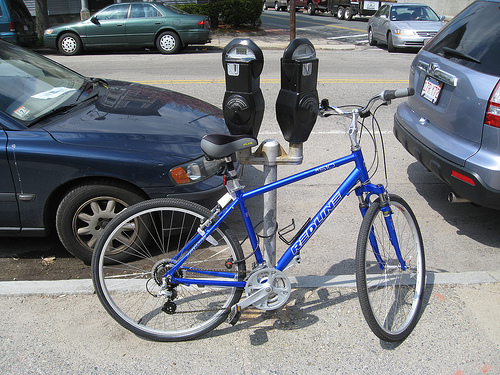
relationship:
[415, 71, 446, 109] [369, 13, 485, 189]
tag on vehicle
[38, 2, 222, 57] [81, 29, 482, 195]
car on street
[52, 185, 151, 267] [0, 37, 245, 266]
tire on car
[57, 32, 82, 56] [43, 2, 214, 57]
tire on car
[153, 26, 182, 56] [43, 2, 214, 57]
tire on car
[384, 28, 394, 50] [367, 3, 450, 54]
tire on car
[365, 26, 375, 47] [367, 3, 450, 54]
tire on car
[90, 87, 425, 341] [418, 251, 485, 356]
bicycle on sidewalk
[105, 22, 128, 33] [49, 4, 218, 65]
handle door on car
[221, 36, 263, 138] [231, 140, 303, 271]
parking meter on a post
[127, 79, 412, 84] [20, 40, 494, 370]
lines on a street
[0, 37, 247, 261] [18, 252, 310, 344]
car next to a curb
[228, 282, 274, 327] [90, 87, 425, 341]
foot peddles on bicycle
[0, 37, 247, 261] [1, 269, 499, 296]
car parked next to curb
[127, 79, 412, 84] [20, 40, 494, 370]
lines painted on street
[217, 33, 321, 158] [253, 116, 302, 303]
meter on pole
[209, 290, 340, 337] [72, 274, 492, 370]
shadow on sidewalk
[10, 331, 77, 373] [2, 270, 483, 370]
gravel on sidewalk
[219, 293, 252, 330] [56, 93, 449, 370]
pedal on bike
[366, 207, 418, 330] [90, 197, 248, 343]
spokes on tire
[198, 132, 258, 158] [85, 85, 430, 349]
seat on bike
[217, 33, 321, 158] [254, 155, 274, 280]
meter on post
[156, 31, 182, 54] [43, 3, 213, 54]
tire on car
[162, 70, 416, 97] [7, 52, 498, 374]
paint on road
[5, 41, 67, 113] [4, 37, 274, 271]
windshield on car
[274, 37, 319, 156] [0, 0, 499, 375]
meter on road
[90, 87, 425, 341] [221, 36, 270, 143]
bicycle next to parking meter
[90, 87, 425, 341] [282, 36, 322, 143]
bicycle next to parking meter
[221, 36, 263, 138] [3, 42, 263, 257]
parking meter near car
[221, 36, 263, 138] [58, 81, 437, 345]
parking meter near bicycle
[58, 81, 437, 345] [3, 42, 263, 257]
bicycle near car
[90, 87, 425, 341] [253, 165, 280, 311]
bicycle chained to pole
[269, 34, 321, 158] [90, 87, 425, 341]
meter near bicycle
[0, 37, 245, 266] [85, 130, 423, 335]
car parked by bicycle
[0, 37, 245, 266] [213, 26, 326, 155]
car parked by parking meters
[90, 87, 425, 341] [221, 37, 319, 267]
bicycle leaning against parking meters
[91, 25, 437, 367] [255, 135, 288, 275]
parking meter on a pole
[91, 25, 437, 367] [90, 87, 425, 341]
parking meter near bicycle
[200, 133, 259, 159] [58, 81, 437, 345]
seat on top of bicycle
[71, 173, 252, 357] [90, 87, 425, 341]
tire connected to bicycle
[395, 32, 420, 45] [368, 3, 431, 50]
headlight on front of car